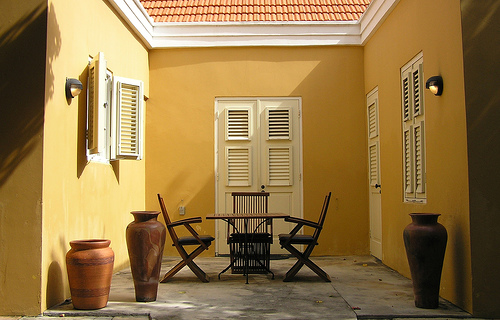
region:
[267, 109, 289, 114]
white wooden slat on shudder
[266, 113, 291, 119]
white wooden slat on shudder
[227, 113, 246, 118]
white wooden slat on shudder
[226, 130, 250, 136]
white wooden slat on shudder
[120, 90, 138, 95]
white wooden slat on shudder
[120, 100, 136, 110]
white wooden slat on shudder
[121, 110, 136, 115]
white wooden slat on shudder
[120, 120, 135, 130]
white wooden slat on shudder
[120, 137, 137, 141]
white wooden slat on shudder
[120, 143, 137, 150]
white wooden slat on shudder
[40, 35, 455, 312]
Three chairs sitting on the side of table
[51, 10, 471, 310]
Wooden table surrounded by three chairs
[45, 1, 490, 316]
Vases standing next to table and chairs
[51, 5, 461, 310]
A wooden table outside a house door in the afternoon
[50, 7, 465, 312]
A house exterior with vases table and chairs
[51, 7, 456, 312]
An outdoor patio with white doors and windows.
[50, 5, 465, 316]
An exterior view of patio with vases and wooden table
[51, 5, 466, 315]
Different colored vases sitting around a wooden table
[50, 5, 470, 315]
Wooden table surrounded by chairs outside a house door.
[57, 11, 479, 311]
A yellow exterior patio adorned with a wooden table and vases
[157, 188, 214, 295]
a brown wooden folding chair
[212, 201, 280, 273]
a small brown wooden table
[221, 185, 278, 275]
a chair made out of metal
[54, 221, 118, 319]
a medium sized urn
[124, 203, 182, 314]
a tall sized brown urn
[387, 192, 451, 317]
a tall sized dark brown urn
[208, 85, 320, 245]
a white door with shutters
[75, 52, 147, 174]
a white window with shutters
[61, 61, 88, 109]
a small light next to a window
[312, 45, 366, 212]
a wall that is painted yellow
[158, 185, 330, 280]
three chairs around a table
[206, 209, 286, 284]
patio table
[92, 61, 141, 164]
a window with open shutters on the left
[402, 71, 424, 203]
window on right with closed shutters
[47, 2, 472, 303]
small courtyard with yellow walls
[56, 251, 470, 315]
gray concrete patio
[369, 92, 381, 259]
white door on right wall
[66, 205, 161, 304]
two vases on the left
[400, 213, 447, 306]
a single vase on the right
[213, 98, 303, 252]
a white double door on the back wall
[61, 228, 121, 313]
a large rust colored vase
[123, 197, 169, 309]
a tall brown vase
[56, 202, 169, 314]
2 vases next to each other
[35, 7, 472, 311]
backyard porch area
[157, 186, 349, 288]
outdoor table and chairs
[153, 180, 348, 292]
outdoor furniture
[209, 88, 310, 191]
blinds on a white door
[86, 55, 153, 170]
window with shutters open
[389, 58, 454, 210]
window shutters and outdoor light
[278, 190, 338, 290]
outdoor patio chair